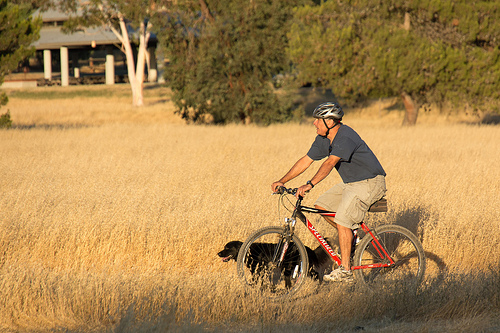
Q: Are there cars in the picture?
A: No, there are no cars.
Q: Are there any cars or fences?
A: No, there are no cars or fences.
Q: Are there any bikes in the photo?
A: Yes, there is a bike.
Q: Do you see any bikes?
A: Yes, there is a bike.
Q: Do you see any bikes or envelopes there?
A: Yes, there is a bike.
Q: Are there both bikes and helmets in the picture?
A: Yes, there are both a bike and a helmet.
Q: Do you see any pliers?
A: No, there are no pliers.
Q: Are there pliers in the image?
A: No, there are no pliers.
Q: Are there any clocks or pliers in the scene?
A: No, there are no pliers or clocks.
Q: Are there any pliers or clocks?
A: No, there are no pliers or clocks.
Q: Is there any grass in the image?
A: Yes, there is grass.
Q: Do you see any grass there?
A: Yes, there is grass.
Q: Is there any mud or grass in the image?
A: Yes, there is grass.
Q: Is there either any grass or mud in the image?
A: Yes, there is grass.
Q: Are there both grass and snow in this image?
A: No, there is grass but no snow.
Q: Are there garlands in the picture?
A: No, there are no garlands.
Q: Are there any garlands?
A: No, there are no garlands.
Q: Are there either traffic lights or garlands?
A: No, there are no garlands or traffic lights.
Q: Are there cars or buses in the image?
A: No, there are no cars or buses.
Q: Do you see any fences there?
A: No, there are no fences.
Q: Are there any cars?
A: No, there are no cars.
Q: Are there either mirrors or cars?
A: No, there are no cars or mirrors.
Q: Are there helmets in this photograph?
A: Yes, there is a helmet.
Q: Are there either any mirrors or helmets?
A: Yes, there is a helmet.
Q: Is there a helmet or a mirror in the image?
A: Yes, there is a helmet.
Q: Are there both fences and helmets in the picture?
A: No, there is a helmet but no fences.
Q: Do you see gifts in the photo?
A: No, there are no gifts.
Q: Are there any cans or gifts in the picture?
A: No, there are no gifts or cans.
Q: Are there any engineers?
A: No, there are no engineers.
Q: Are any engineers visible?
A: No, there are no engineers.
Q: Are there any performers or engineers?
A: No, there are no engineers or performers.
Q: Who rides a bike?
A: The man rides a bike.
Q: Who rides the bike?
A: The man rides a bike.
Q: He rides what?
A: The man rides a bike.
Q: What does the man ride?
A: The man rides a bike.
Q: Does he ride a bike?
A: Yes, the man rides a bike.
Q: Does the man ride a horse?
A: No, the man rides a bike.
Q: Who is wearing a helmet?
A: The man is wearing a helmet.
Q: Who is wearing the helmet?
A: The man is wearing a helmet.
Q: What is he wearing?
A: The man is wearing a helmet.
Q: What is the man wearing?
A: The man is wearing a helmet.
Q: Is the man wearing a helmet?
A: Yes, the man is wearing a helmet.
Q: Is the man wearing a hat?
A: No, the man is wearing a helmet.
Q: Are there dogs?
A: Yes, there is a dog.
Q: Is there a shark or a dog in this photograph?
A: Yes, there is a dog.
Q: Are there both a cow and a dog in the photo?
A: No, there is a dog but no cows.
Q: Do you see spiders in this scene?
A: No, there are no spiders.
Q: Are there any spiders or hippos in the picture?
A: No, there are no spiders or hippos.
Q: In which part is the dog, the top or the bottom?
A: The dog is in the bottom of the image.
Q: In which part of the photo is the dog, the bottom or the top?
A: The dog is in the bottom of the image.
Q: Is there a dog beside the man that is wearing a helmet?
A: Yes, there is a dog beside the man.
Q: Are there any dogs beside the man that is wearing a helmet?
A: Yes, there is a dog beside the man.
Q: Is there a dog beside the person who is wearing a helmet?
A: Yes, there is a dog beside the man.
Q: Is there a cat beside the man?
A: No, there is a dog beside the man.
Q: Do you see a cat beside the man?
A: No, there is a dog beside the man.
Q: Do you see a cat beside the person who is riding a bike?
A: No, there is a dog beside the man.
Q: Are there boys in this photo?
A: No, there are no boys.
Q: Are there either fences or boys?
A: No, there are no boys or fences.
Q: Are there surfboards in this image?
A: No, there are no surfboards.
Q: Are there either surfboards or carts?
A: No, there are no surfboards or carts.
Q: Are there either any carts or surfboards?
A: No, there are no surfboards or carts.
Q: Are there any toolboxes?
A: No, there are no toolboxes.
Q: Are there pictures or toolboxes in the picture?
A: No, there are no toolboxes or pictures.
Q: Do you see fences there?
A: No, there are no fences.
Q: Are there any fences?
A: No, there are no fences.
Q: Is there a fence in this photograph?
A: No, there are no fences.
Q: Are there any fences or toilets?
A: No, there are no fences or toilets.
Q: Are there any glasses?
A: No, there are no glasses.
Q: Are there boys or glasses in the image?
A: No, there are no glasses or boys.